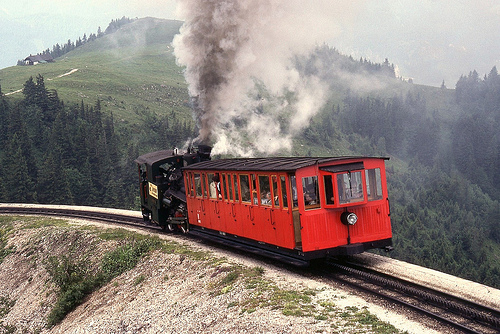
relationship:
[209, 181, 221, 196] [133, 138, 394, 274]
passengers on train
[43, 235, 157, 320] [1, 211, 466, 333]
grass on slope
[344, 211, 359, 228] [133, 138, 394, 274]
light on train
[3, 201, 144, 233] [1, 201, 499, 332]
curved track on railroad